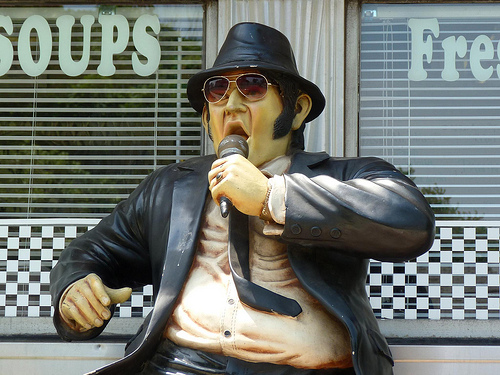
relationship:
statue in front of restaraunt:
[48, 22, 439, 374] [1, 1, 499, 340]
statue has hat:
[48, 22, 439, 374] [186, 21, 327, 124]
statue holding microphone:
[48, 22, 439, 374] [217, 135, 250, 218]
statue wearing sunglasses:
[48, 22, 439, 374] [196, 72, 280, 104]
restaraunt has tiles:
[1, 1, 499, 340] [0, 218, 499, 322]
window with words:
[1, 1, 206, 226] [0, 14, 166, 77]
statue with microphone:
[48, 22, 439, 374] [217, 135, 250, 218]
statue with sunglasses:
[48, 22, 439, 374] [196, 72, 280, 104]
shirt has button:
[159, 151, 356, 370] [223, 328, 233, 338]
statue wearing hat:
[48, 22, 439, 374] [186, 21, 327, 124]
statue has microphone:
[48, 22, 439, 374] [217, 135, 250, 218]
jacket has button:
[44, 150, 437, 375] [288, 222, 303, 240]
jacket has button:
[44, 150, 437, 375] [308, 226, 325, 241]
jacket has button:
[44, 150, 437, 375] [330, 224, 341, 241]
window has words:
[1, 1, 206, 226] [0, 14, 166, 77]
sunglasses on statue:
[196, 72, 280, 104] [48, 22, 439, 374]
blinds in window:
[0, 17, 204, 219] [1, 1, 206, 226]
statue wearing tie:
[48, 22, 439, 374] [226, 203, 305, 318]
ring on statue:
[213, 172, 223, 185] [48, 22, 439, 374]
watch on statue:
[260, 178, 279, 227] [48, 22, 439, 374]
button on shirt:
[223, 328, 233, 338] [159, 151, 356, 370]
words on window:
[0, 14, 166, 77] [1, 1, 206, 226]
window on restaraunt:
[1, 1, 206, 226] [1, 1, 499, 340]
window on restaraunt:
[358, 2, 498, 223] [1, 1, 499, 340]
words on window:
[406, 16, 499, 85] [358, 2, 498, 223]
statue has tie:
[48, 22, 439, 374] [226, 203, 305, 318]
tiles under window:
[0, 218, 499, 322] [1, 1, 206, 226]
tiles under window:
[0, 218, 499, 322] [358, 2, 498, 223]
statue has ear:
[48, 22, 439, 374] [198, 99, 209, 133]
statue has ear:
[48, 22, 439, 374] [292, 90, 313, 132]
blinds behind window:
[0, 17, 204, 219] [1, 1, 206, 226]